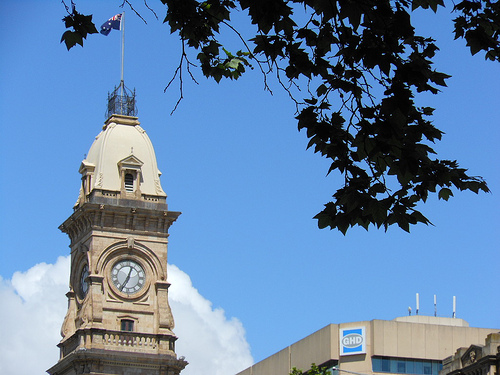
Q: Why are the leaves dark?
A: Shadows.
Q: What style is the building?
A: Modern.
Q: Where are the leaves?
A: On the tree branches.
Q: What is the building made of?
A: Concrete.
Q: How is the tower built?
A: Ornately.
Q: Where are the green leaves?
A: On the tree.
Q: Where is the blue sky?
A: Above the buildings.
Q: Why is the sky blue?
A: Only one cloud.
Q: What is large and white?
A: Cloud.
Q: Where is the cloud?
A: Sky.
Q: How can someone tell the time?
A: Clock.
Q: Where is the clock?
A: On the tower.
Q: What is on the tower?
A: A clock.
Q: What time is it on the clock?
A: 12:35 PM.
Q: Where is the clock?
A: On the tower.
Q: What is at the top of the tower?
A: An antenna.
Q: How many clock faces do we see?
A: Two.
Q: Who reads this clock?
A: People in the area.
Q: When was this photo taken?
A: During the daytime.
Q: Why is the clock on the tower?
A: To show time.